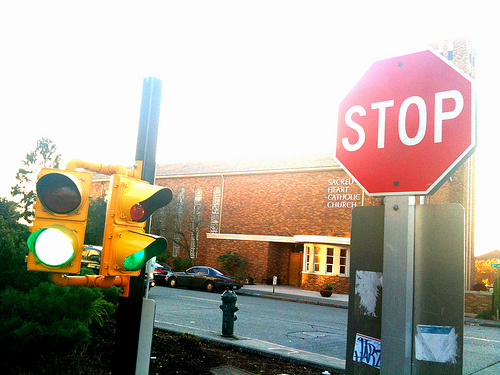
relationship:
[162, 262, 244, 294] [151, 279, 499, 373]
car parked on street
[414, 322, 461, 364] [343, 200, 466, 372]
paper stuck on sign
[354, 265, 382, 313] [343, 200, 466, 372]
paper stuck on sign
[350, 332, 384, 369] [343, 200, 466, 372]
graffiti stuck on sign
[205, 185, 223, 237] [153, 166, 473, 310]
window on building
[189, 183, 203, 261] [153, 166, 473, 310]
window on building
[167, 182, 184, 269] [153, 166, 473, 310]
window on building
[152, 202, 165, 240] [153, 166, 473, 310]
window on building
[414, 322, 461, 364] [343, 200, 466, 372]
paper on sign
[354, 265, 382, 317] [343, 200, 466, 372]
paper on sign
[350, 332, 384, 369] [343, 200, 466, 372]
graffiti on sign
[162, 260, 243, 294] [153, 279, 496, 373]
car parked beside road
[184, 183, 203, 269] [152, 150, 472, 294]
window on building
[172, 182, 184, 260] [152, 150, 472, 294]
window on building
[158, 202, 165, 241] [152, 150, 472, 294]
window on building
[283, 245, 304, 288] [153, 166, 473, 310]
doorway on building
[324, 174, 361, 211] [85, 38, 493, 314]
lettering on building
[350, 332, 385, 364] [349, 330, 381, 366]
graffiti on sticker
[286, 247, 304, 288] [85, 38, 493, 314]
doorway of building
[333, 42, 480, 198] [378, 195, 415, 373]
red/stop sign on a post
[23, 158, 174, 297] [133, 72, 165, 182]
lights on a pole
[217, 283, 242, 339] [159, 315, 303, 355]
fire hydrant on a sidewalk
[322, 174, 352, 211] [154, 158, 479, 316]
lettering on a building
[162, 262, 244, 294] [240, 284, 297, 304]
car at curb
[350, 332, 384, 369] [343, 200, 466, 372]
graffiti on back of a sign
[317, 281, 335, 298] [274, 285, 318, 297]
planter on sidewalk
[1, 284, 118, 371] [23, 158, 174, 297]
bushes near lights